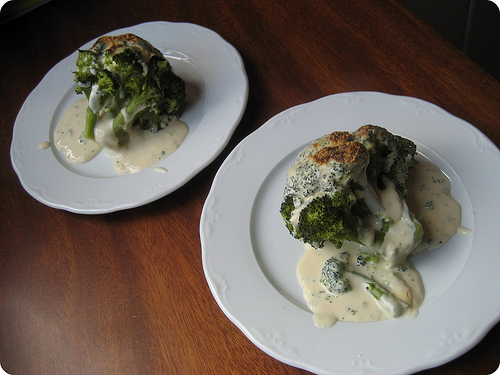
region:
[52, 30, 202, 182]
broccoli laying in cream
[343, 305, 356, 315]
green bits in the cream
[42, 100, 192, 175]
puddle of cream on the plate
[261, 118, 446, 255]
huge hunk of broccoli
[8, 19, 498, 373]
two white circular plates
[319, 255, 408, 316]
small piece of broccoli in the cream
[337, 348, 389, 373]
engraving on the edge of the plate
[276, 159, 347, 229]
cream on the head of the broccoli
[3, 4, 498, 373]
dark brown wood on the tabletop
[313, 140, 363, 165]
brown spot on the broccoli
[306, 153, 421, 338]
Broccoli and gravy in the plate.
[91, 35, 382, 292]
Both plates have broccoli and gravy.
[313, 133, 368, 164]
The floret of the broccoli is burned.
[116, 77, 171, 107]
Green floret on the broccoli.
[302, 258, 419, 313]
White gravy on the plate.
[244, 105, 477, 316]
The plate is white and round.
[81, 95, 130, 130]
Stem of the broccoli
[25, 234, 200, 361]
The table is brown.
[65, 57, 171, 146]
Gravy and broccoli on the plate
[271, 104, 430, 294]
cream and broccoli on a plate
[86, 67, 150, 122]
cream and broccoli on a plate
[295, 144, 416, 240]
cream and broccoli on a plate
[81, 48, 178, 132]
cream and broccoli on a plate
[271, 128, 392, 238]
cream and broccoli on a plate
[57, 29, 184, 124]
cream and broccoli on a plate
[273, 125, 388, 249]
cream and broccoli on a plate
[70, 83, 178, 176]
cream and broccoli on a plate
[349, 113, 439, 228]
cream and broccoli on a plate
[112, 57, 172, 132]
cream and broccoli on a plate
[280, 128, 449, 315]
Broccoli on the plate.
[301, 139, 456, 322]
Broccolli and white gravy on the plate.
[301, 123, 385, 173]
The broccoli is burned.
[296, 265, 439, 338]
The gravy is on the plate.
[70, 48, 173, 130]
The broccoli has florets.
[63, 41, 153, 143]
The broccoli is green.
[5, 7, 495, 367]
brown surface of table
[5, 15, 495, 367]
two round plates of food on table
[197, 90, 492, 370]
slightly raised design around edge of plate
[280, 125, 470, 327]
melted sauce over vegetable and plate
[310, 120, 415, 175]
browned spots over florets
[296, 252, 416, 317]
small piece of broccoli in pool of sauce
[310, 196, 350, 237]
part of broccoli not covered in sauce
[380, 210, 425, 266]
blunt end of cut broccoli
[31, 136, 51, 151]
dot of sauce on rim of plate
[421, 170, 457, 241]
sauce with tiny bits of florets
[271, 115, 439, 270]
a large piece of broccoli covered in a cream sauce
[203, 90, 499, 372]
White plate on a wooden table.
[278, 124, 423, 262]
Broccoli with cream on top.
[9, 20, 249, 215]
White plate with a floral design.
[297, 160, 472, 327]
Cream on a white plate.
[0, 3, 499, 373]
A dark colored wooden table.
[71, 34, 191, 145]
Steamed broccoli on a plate.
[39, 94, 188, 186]
Cream sauce on a white plate.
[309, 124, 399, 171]
Spices on the side of a broccoli.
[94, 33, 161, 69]
Paprika on a piece of broccoli.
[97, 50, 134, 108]
broccoli with cream on a plate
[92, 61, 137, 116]
broccoli with cream on a plate in the left side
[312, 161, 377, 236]
broccoli with cream on a plate in the right side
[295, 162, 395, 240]
broccoli with cream on a plate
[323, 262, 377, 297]
small broccoli on the plate